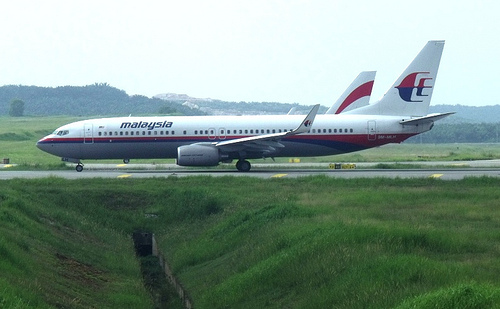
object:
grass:
[0, 174, 499, 309]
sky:
[0, 0, 499, 108]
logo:
[394, 71, 433, 102]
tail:
[339, 39, 445, 117]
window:
[224, 127, 234, 134]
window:
[220, 130, 224, 135]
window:
[183, 130, 187, 135]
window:
[350, 128, 353, 133]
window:
[339, 129, 342, 133]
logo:
[120, 120, 173, 130]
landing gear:
[75, 165, 83, 172]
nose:
[35, 132, 51, 152]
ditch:
[132, 230, 196, 308]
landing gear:
[236, 160, 251, 172]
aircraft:
[35, 40, 456, 172]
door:
[83, 124, 94, 144]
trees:
[0, 78, 210, 116]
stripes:
[40, 132, 416, 148]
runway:
[0, 169, 499, 179]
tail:
[325, 71, 377, 115]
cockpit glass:
[51, 129, 69, 136]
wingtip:
[292, 103, 320, 133]